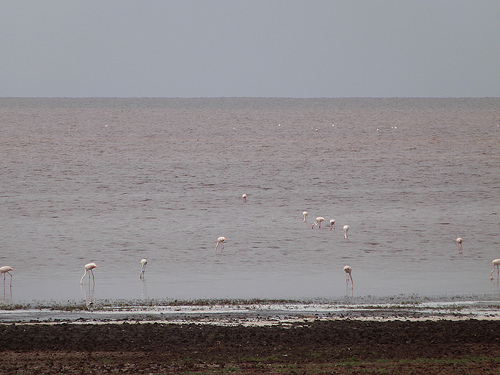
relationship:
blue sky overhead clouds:
[0, 0, 500, 95] [300, 16, 397, 56]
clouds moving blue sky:
[249, 36, 359, 79] [0, 0, 500, 95]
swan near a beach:
[16, 258, 114, 270] [25, 116, 498, 375]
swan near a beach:
[133, 253, 156, 288] [26, 207, 496, 370]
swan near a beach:
[329, 245, 360, 365] [22, 246, 499, 375]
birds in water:
[24, 212, 382, 313] [17, 144, 498, 254]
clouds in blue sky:
[0, 0, 500, 91] [189, 123, 250, 135]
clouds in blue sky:
[0, 0, 500, 91] [44, 50, 149, 73]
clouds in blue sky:
[0, 0, 500, 91] [299, 100, 339, 112]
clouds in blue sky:
[0, 0, 500, 91] [162, 50, 229, 82]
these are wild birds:
[69, 194, 218, 375] [39, 116, 437, 321]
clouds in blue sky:
[0, 0, 500, 91] [222, 101, 313, 110]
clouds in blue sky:
[0, 0, 500, 91] [42, 50, 83, 73]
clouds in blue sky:
[0, 0, 500, 91] [40, 105, 109, 122]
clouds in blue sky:
[0, 0, 500, 91] [16, 62, 164, 93]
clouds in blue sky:
[0, 0, 500, 91] [239, 101, 289, 103]